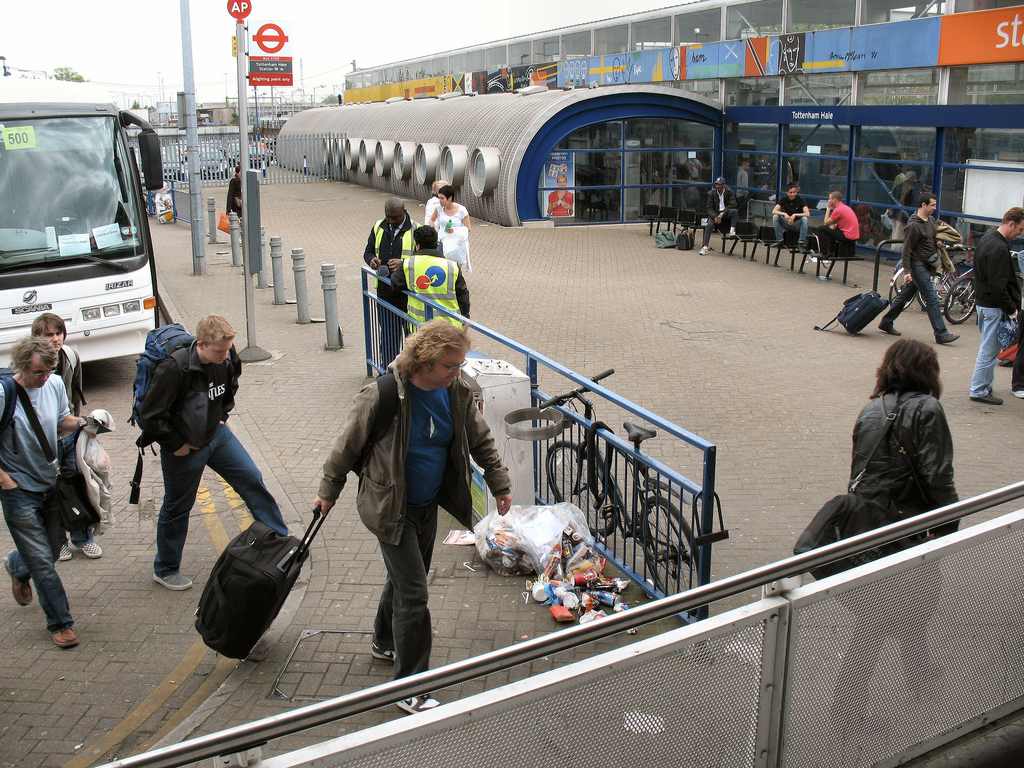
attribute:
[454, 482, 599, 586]
trash bag — plastic  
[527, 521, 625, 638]
trash — spilled 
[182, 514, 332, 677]
suitcase — black 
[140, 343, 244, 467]
shirt — black 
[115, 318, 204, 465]
backpack — blue 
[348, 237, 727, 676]
fence — silver , metal 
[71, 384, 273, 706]
lines — double  , yellow 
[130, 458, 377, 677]
suitcase — black  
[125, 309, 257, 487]
jacket — black  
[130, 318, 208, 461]
suitcase — blue 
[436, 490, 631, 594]
trash bag — torn 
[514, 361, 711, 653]
bike — black 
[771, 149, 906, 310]
men — sitting , talking 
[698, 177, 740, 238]
jacket — black 